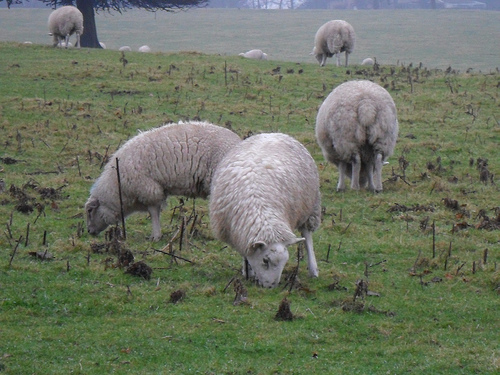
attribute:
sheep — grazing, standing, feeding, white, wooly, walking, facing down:
[47, 5, 84, 48]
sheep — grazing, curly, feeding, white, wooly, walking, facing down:
[208, 131, 324, 289]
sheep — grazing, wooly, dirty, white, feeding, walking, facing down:
[82, 120, 244, 244]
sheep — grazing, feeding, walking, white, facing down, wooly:
[315, 78, 401, 192]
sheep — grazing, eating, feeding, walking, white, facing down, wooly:
[312, 19, 354, 67]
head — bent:
[245, 229, 303, 288]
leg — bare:
[138, 184, 166, 243]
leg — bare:
[300, 225, 326, 277]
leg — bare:
[349, 155, 363, 189]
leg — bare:
[335, 163, 346, 193]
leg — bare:
[373, 153, 387, 192]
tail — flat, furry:
[357, 98, 379, 126]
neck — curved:
[230, 205, 287, 247]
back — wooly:
[328, 87, 402, 187]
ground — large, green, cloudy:
[6, 8, 499, 373]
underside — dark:
[339, 146, 377, 171]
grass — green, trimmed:
[2, 40, 497, 374]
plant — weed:
[16, 203, 46, 213]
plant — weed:
[124, 260, 153, 278]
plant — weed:
[348, 279, 367, 303]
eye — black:
[261, 258, 269, 268]